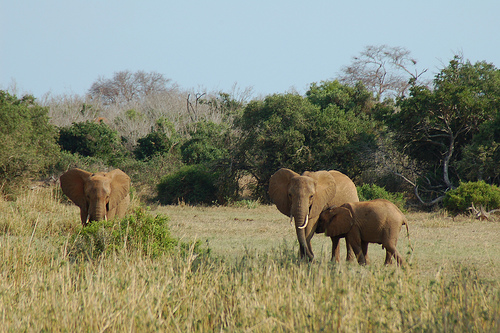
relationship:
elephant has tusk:
[61, 167, 136, 227] [85, 215, 91, 226]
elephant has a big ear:
[61, 167, 136, 227] [61, 168, 87, 208]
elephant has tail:
[315, 199, 409, 272] [401, 218, 410, 237]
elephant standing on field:
[61, 167, 136, 227] [0, 204, 496, 333]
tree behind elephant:
[57, 120, 114, 159] [61, 167, 136, 227]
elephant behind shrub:
[61, 167, 136, 227] [50, 208, 179, 262]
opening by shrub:
[138, 200, 298, 263] [50, 208, 179, 262]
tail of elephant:
[401, 218, 410, 237] [315, 199, 409, 272]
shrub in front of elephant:
[50, 208, 179, 262] [61, 167, 136, 227]